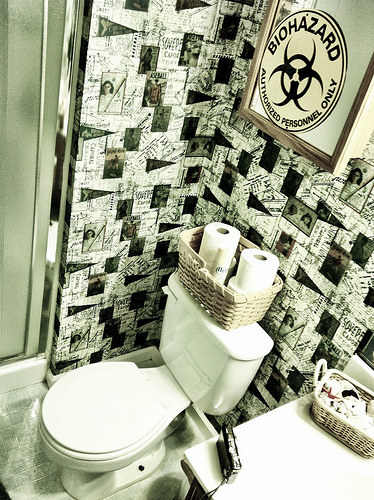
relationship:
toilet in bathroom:
[37, 270, 275, 499] [1, 0, 374, 499]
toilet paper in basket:
[236, 249, 278, 294] [177, 224, 282, 332]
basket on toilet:
[177, 224, 282, 332] [37, 270, 275, 499]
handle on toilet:
[161, 285, 179, 303] [37, 270, 275, 499]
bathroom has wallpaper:
[1, 0, 374, 499] [50, 0, 373, 434]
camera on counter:
[218, 422, 238, 482] [183, 353, 373, 499]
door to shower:
[0, 1, 76, 368] [1, 1, 80, 394]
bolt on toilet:
[137, 463, 146, 471] [37, 270, 275, 499]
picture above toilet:
[260, 8, 347, 132] [37, 270, 275, 499]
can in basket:
[211, 246, 234, 285] [177, 224, 282, 332]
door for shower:
[0, 1, 76, 368] [1, 1, 80, 394]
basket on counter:
[311, 357, 373, 459] [183, 353, 373, 499]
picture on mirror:
[260, 8, 347, 132] [236, 2, 373, 175]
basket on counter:
[177, 224, 282, 332] [183, 353, 373, 499]